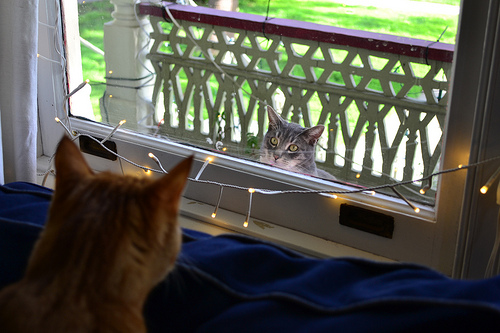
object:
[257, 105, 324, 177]
cat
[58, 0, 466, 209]
window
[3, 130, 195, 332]
cat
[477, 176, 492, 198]
lights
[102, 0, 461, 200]
railing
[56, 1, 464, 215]
patio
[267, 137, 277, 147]
eyes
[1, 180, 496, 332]
blanket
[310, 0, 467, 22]
sun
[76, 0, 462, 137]
grass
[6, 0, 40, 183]
curtain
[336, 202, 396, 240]
handles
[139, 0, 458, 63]
border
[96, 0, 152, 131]
pillar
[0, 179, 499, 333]
couch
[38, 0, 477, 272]
frame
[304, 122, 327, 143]
ear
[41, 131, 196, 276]
head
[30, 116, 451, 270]
edge